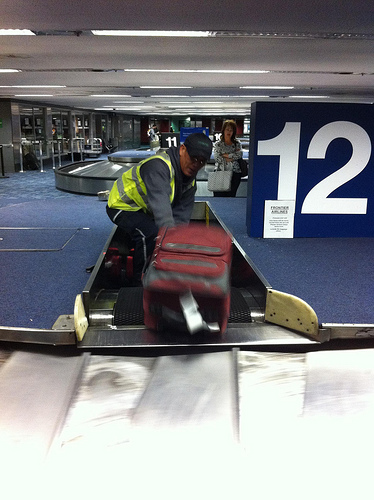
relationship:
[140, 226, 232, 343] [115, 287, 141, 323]
luggage exiting belt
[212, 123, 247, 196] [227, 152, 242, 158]
woman standing arm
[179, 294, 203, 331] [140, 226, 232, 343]
tag on luggage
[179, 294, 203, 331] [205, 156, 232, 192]
tag on bag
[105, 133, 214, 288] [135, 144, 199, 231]
man wearing shirt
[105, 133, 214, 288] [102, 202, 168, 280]
man wearing pants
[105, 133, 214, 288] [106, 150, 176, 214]
man wearing vest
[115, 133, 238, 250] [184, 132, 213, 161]
man wearing cap